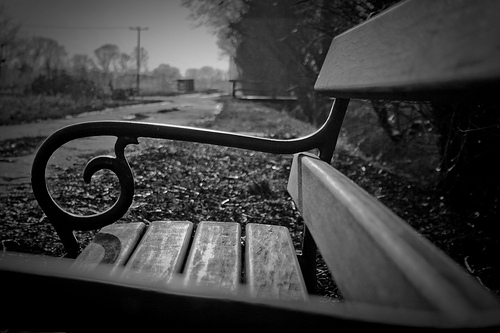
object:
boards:
[71, 219, 308, 301]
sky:
[62, 30, 125, 42]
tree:
[92, 44, 121, 84]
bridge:
[228, 79, 294, 99]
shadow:
[91, 233, 121, 271]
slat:
[313, 0, 500, 100]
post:
[124, 26, 151, 98]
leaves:
[151, 154, 233, 190]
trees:
[148, 63, 183, 96]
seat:
[69, 217, 309, 302]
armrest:
[30, 97, 350, 254]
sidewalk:
[0, 103, 205, 194]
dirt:
[123, 101, 192, 117]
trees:
[10, 35, 68, 71]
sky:
[148, 31, 209, 51]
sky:
[46, 1, 156, 14]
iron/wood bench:
[0, 0, 500, 333]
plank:
[241, 219, 304, 297]